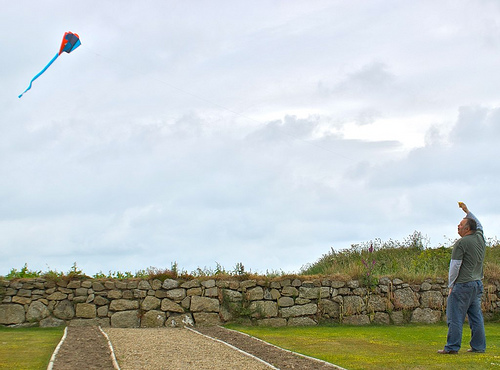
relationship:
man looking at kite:
[443, 202, 492, 354] [11, 30, 82, 100]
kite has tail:
[11, 30, 82, 100] [17, 49, 67, 98]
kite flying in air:
[11, 30, 82, 100] [0, 1, 496, 275]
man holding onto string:
[443, 202, 492, 354] [59, 51, 464, 207]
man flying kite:
[443, 202, 492, 354] [11, 30, 82, 100]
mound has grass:
[302, 245, 499, 277] [313, 248, 497, 277]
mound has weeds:
[302, 245, 499, 277] [405, 229, 427, 261]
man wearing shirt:
[443, 202, 492, 354] [446, 259, 462, 290]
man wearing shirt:
[443, 202, 492, 354] [451, 232, 487, 284]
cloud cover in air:
[1, 101, 496, 225] [0, 1, 496, 275]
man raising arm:
[443, 202, 492, 354] [458, 200, 488, 238]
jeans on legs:
[446, 277, 487, 354] [444, 279, 489, 356]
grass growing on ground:
[1, 326, 67, 369] [1, 327, 497, 367]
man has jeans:
[443, 202, 492, 354] [446, 277, 487, 354]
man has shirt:
[443, 202, 492, 354] [446, 259, 462, 290]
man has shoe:
[443, 202, 492, 354] [436, 348, 459, 355]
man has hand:
[443, 202, 492, 354] [459, 202, 469, 216]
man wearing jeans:
[443, 202, 492, 354] [446, 277, 487, 354]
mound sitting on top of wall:
[302, 245, 499, 277] [1, 275, 498, 325]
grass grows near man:
[219, 322, 498, 368] [443, 202, 492, 354]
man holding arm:
[443, 202, 492, 354] [458, 200, 488, 238]